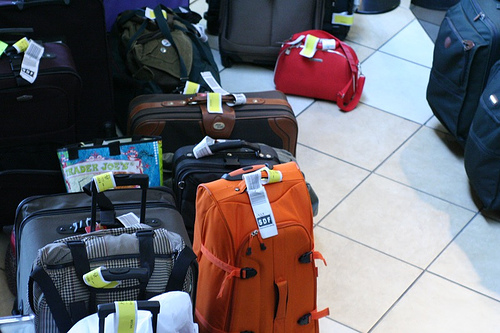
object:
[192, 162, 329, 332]
luggage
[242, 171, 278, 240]
tag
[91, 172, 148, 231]
luggage handle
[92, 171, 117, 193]
tag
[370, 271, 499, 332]
tile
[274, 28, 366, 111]
bag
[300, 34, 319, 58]
tag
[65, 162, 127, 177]
trader joe's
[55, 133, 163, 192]
bag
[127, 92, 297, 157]
luggage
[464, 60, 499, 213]
luggage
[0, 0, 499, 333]
floor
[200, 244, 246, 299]
strap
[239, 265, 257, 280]
buckle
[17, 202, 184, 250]
zipper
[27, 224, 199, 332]
bag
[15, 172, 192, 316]
luggage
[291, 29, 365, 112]
strap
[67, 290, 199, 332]
luggage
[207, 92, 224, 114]
tag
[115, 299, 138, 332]
tag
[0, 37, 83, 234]
luggage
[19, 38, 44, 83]
tag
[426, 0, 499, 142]
luggage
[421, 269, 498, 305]
lines